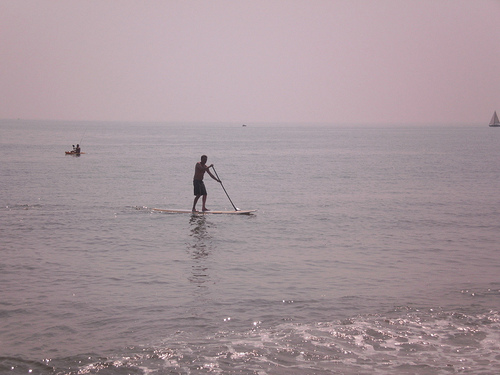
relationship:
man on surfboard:
[194, 155, 221, 212] [138, 205, 255, 217]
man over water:
[194, 155, 221, 212] [1, 122, 499, 373]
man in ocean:
[194, 155, 221, 212] [0, 119, 499, 369]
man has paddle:
[194, 155, 221, 212] [211, 165, 238, 213]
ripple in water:
[14, 353, 300, 374] [1, 122, 499, 373]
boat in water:
[491, 115, 500, 129] [1, 122, 499, 373]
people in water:
[65, 141, 84, 157] [1, 122, 499, 373]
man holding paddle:
[194, 155, 221, 212] [211, 165, 238, 213]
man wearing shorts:
[194, 155, 221, 212] [192, 179, 208, 197]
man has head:
[194, 155, 221, 212] [199, 154, 211, 167]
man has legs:
[194, 155, 221, 212] [191, 195, 214, 215]